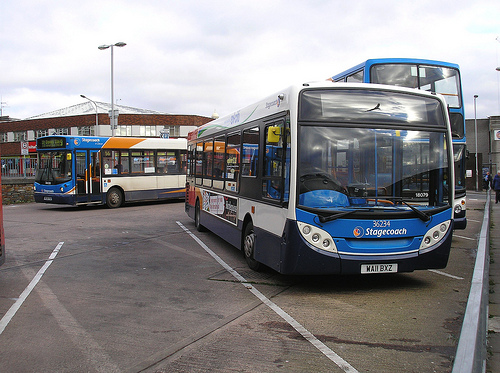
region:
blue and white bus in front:
[184, 83, 451, 278]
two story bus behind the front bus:
[322, 58, 469, 228]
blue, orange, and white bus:
[34, 135, 187, 207]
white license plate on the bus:
[358, 262, 396, 274]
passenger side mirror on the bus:
[266, 123, 283, 145]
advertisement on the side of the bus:
[199, 189, 238, 226]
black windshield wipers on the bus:
[316, 193, 430, 227]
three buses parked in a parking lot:
[33, 56, 465, 277]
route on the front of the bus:
[39, 136, 64, 148]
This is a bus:
[20, 131, 227, 214]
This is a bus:
[175, 83, 470, 298]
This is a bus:
[290, 53, 498, 230]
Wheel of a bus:
[91, 176, 144, 229]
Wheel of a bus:
[230, 194, 267, 270]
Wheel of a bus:
[190, 189, 213, 240]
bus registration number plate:
[352, 259, 416, 281]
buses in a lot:
[30, 59, 472, 278]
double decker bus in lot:
[310, 31, 475, 231]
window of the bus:
[306, 132, 431, 200]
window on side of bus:
[191, 140, 273, 175]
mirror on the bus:
[264, 116, 284, 151]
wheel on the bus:
[234, 225, 262, 273]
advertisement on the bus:
[199, 191, 238, 220]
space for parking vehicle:
[68, 240, 204, 345]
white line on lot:
[201, 260, 334, 348]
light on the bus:
[299, 228, 451, 250]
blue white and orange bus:
[185, 82, 449, 274]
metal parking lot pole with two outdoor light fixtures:
[94, 40, 128, 133]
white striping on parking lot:
[1, 194, 498, 371]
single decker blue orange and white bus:
[36, 135, 186, 205]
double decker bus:
[325, 57, 466, 227]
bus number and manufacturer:
[353, 219, 410, 238]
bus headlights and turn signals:
[298, 226, 450, 244]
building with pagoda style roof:
[1, 101, 215, 150]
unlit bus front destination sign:
[320, 96, 428, 121]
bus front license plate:
[359, 260, 400, 274]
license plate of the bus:
[361, 262, 400, 275]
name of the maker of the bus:
[351, 222, 419, 240]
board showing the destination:
[321, 92, 429, 120]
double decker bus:
[327, 55, 464, 90]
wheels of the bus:
[102, 184, 129, 208]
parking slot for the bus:
[42, 227, 254, 369]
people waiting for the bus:
[479, 162, 499, 203]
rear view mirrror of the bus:
[264, 122, 284, 143]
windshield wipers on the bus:
[317, 198, 437, 225]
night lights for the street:
[94, 28, 130, 58]